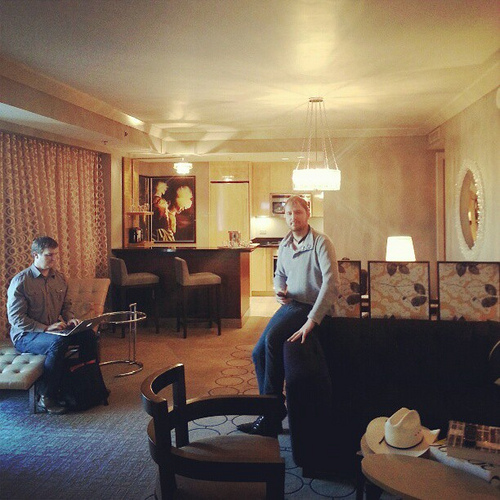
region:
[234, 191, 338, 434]
Man leaning on a couch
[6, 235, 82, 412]
Man sitting on a chair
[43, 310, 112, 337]
Laptop on the man's lap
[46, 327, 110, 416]
Backpack on the floor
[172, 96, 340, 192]
Lights hanging from the ceiling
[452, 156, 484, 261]
Mirror on the wall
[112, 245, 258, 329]
Bar counter in the living room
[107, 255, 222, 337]
Chairs under the counter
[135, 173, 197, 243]
Picture on the wall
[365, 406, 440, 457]
White hat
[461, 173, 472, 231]
mirror on the wall.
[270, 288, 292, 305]
phone in the man's hand.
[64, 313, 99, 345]
laptop on man's lap.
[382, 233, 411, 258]
lamp shade near the wall.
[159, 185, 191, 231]
portrait on the wall.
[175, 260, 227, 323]
tall chair near bar.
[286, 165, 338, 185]
light hanging from ceiling.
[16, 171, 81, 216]
curtains over the window.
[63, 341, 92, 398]
backpack on the ground.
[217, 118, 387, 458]
a man sitting on a couch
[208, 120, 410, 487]
a man sitting on the arm of a couch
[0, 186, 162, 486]
a man on a computer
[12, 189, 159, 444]
a man sitting on a laptop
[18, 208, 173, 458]
a man typing on a computer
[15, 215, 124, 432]
a man typing on a laptop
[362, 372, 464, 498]
a white cowboy hat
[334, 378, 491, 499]
a cowboy hat on the table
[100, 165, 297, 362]
a bar with stools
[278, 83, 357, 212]
chandlier hanging from ceiling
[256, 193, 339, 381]
man sitting on a couch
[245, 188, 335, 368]
man wearing a shirt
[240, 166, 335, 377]
man wearing blue jeans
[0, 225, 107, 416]
man sitting on a chair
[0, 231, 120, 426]
man wearing a shirt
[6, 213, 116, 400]
man looking at a lap top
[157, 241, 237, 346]
bar stool next to bar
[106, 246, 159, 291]
bar stool next to bar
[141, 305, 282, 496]
chair next to couch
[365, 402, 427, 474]
hat on a chair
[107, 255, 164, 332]
a padded bar stool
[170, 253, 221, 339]
a padded bar stool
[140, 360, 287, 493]
a wooden chair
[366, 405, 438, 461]
a white cowboy hat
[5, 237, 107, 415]
a man using laptop computer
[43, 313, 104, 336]
an Apple MacBook computer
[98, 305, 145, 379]
a chrome and glass table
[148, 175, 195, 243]
a picture on wall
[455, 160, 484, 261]
a mirror on wall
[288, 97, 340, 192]
a lit hanging chandelier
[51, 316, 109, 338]
man working on gray laptop computer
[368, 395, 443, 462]
tan cowboy hat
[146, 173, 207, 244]
painting on wall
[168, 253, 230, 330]
large tan barstool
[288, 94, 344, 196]
chandelier light fixture hanging from ceiling